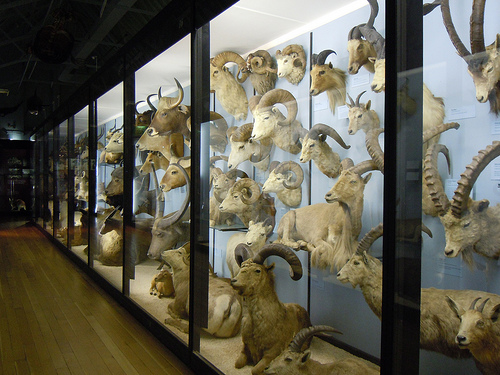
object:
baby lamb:
[149, 268, 173, 299]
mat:
[0, 216, 201, 374]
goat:
[444, 292, 499, 370]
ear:
[444, 295, 465, 320]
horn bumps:
[420, 141, 452, 217]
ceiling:
[0, 0, 237, 140]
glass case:
[126, 34, 190, 345]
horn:
[446, 141, 499, 218]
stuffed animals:
[36, 0, 500, 373]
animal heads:
[272, 46, 307, 86]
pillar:
[380, 2, 427, 374]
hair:
[324, 84, 349, 116]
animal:
[259, 160, 305, 210]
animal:
[226, 242, 313, 369]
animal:
[153, 242, 234, 335]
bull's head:
[145, 76, 189, 138]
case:
[32, 1, 498, 373]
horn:
[251, 241, 303, 285]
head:
[306, 47, 350, 97]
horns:
[272, 160, 304, 189]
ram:
[259, 322, 378, 372]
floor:
[0, 219, 198, 374]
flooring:
[1, 219, 209, 375]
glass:
[418, 0, 500, 374]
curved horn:
[314, 49, 335, 67]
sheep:
[322, 157, 383, 237]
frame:
[184, 23, 212, 354]